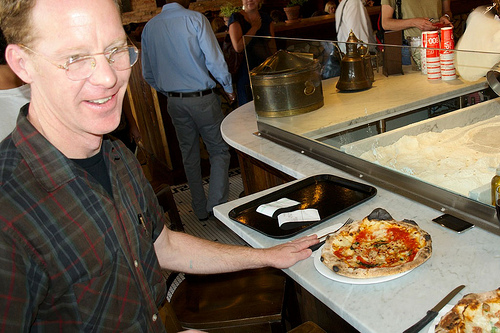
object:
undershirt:
[64, 151, 136, 198]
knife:
[402, 284, 465, 332]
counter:
[210, 173, 455, 319]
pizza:
[434, 287, 500, 332]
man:
[140, 0, 236, 222]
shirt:
[137, 7, 237, 93]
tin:
[247, 48, 324, 120]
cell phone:
[431, 213, 476, 235]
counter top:
[211, 64, 497, 331]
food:
[318, 215, 432, 278]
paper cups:
[420, 31, 457, 80]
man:
[0, 0, 322, 331]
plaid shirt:
[0, 101, 168, 332]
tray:
[228, 173, 379, 239]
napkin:
[306, 223, 347, 243]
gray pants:
[165, 89, 230, 218]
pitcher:
[335, 29, 374, 93]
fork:
[317, 217, 354, 240]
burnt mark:
[331, 266, 340, 274]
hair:
[0, 0, 35, 55]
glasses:
[12, 36, 141, 81]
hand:
[260, 233, 324, 269]